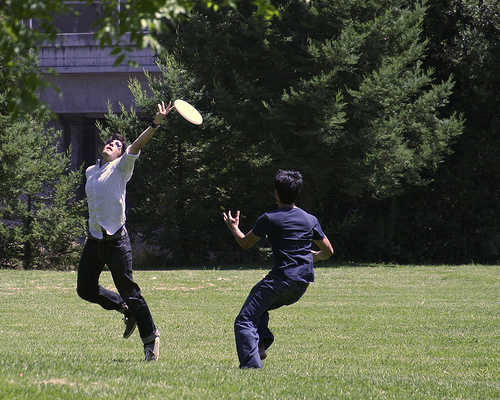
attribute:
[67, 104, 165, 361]
man — jumping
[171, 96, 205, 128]
frisbee — white, yellow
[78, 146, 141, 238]
shirt — white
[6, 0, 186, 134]
building — concrete